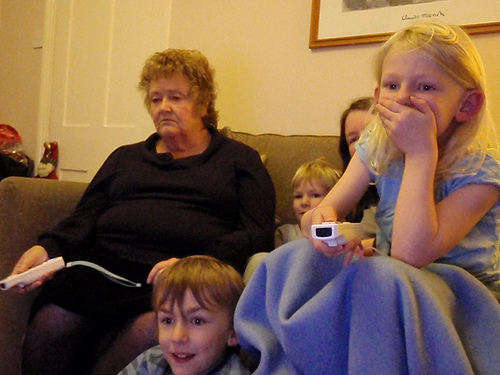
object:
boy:
[113, 252, 253, 374]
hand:
[376, 96, 440, 154]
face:
[381, 45, 464, 143]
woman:
[2, 49, 277, 374]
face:
[149, 75, 194, 136]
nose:
[159, 99, 170, 114]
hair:
[136, 50, 219, 128]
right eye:
[150, 95, 164, 105]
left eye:
[170, 93, 183, 99]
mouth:
[159, 118, 178, 126]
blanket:
[234, 236, 499, 374]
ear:
[197, 93, 210, 115]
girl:
[234, 20, 500, 374]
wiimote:
[310, 221, 362, 247]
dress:
[356, 139, 500, 297]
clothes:
[34, 132, 277, 323]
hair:
[155, 253, 245, 321]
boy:
[274, 155, 344, 247]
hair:
[292, 155, 343, 190]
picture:
[319, 1, 500, 43]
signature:
[401, 9, 445, 22]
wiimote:
[0, 253, 67, 291]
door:
[36, 2, 174, 177]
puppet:
[34, 139, 60, 179]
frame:
[309, 2, 500, 49]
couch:
[0, 121, 344, 374]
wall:
[174, 5, 499, 143]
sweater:
[34, 122, 277, 268]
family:
[1, 25, 498, 374]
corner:
[310, 29, 328, 47]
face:
[161, 279, 214, 373]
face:
[288, 188, 321, 221]